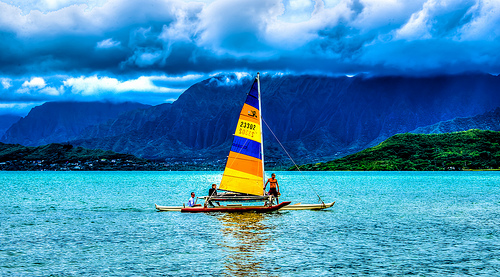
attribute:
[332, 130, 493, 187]
hill — LUSH, GRASSY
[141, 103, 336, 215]
sailboat — small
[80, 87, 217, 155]
moutain — TALL, LARGE 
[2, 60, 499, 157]
mountains — majestic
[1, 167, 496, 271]
water — reflection, crystal, clear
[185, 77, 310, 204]
sail — colorful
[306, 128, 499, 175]
hillside — green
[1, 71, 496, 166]
hillside — grassy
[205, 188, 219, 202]
shirt — white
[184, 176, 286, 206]
sailors — Group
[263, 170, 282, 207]
man — standing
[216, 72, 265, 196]
sail — multi-colored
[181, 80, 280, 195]
sail — STRIPED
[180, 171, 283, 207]
people — three 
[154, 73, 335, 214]
boat — sail